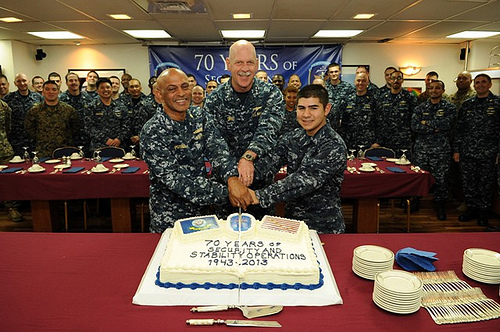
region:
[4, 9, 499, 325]
celebration of military service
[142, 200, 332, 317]
cake ready to be cut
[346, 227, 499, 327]
serving dishes on table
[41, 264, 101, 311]
red tablecloth with cake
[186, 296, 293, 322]
cake knives on table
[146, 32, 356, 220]
men posing for photo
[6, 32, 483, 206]
military men posing for photo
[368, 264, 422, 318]
stack of cake plates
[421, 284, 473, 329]
forks lined up in row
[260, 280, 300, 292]
blue icing border of cake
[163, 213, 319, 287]
70 years of security and stability operations 1943-2013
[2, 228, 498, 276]
The table is red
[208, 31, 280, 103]
This guy is older than the three men in front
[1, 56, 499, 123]
Everyone pictured is in the military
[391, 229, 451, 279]
Blue napkin on the table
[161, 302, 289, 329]
Utensils for cutting the cake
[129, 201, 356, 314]
white napkin underneath the cake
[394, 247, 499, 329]
Utensils are for the soldiers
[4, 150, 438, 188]
This table is for everyone to eat at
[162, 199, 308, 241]
Photographs on the cake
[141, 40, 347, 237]
three guys cutting a cake together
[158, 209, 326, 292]
the cake is white with blue lettering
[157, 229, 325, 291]
blue frosting edges the white cake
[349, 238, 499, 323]
white dishes are in stacks for serving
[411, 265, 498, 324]
forks are lined up for use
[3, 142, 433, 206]
the table is set for serving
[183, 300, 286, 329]
a cake knife and fork are on the table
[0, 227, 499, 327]
the tablecloth under the cake is maroon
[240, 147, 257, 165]
the bald man is wearing a watch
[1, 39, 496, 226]
all the men are wearing camouflage uniforms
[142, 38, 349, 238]
The three men cutting the cake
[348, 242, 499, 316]
The plates on the table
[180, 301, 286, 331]
The utensils in front of the cake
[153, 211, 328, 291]
The cake being cut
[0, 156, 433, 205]
The table behind the people cutting the cake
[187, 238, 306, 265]
The writing on the cake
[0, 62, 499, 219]
The people in the background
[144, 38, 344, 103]
The blue banner mostly blocked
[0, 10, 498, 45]
The lights on the ceiling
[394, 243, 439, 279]
The blue napkin on the cake table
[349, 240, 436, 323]
white stack of plates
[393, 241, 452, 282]
blue stack of napkins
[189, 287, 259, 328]
silver stainless cake servers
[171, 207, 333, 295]
blue and white cake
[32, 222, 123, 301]
red table cloth on table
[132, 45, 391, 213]
three people cutting a cake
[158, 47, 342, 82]
blue large banner behind men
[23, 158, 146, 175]
nicely arranged table settings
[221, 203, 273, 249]
knife cutting the cake